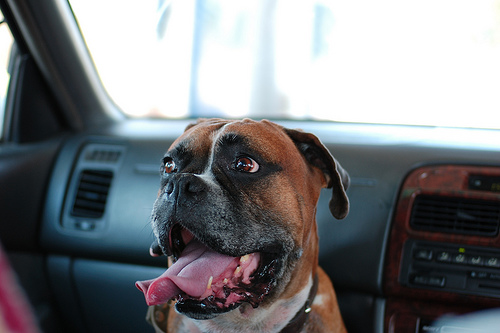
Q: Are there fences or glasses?
A: No, there are no fences or glasses.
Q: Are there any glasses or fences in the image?
A: No, there are no fences or glasses.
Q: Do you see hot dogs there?
A: Yes, there is a hot dog.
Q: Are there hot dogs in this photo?
A: Yes, there is a hot dog.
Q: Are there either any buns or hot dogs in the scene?
A: Yes, there is a hot dog.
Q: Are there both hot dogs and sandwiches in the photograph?
A: No, there is a hot dog but no sandwiches.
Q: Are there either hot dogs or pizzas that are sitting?
A: Yes, the hot dog is sitting.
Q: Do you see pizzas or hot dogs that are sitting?
A: Yes, the hot dog is sitting.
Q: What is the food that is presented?
A: The food is a hot dog.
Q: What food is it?
A: The food is a hot dog.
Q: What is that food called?
A: This is a hot dog.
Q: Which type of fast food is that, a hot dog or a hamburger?
A: This is a hot dog.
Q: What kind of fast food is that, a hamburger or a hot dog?
A: This is a hot dog.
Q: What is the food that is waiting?
A: The food is a hot dog.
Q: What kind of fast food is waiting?
A: The fast food is a hot dog.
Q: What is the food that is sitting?
A: The food is a hot dog.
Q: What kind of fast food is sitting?
A: The fast food is a hot dog.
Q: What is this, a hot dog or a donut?
A: This is a hot dog.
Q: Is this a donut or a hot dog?
A: This is a hot dog.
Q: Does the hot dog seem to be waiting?
A: Yes, the hot dog is waiting.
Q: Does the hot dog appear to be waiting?
A: Yes, the hot dog is waiting.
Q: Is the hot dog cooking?
A: No, the hot dog is waiting.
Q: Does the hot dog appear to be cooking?
A: No, the hot dog is waiting.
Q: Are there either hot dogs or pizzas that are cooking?
A: No, there is a hot dog but it is waiting.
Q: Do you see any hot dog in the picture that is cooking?
A: No, there is a hot dog but it is waiting.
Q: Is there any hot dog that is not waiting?
A: No, there is a hot dog but it is waiting.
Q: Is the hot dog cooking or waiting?
A: The hot dog is waiting.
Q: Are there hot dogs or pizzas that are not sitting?
A: No, there is a hot dog but it is sitting.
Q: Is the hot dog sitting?
A: Yes, the hot dog is sitting.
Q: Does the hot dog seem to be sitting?
A: Yes, the hot dog is sitting.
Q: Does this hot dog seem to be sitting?
A: Yes, the hot dog is sitting.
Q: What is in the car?
A: The hot dog is in the car.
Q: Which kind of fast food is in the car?
A: The food is a hot dog.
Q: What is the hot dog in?
A: The hot dog is in the car.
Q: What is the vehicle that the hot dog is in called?
A: The vehicle is a car.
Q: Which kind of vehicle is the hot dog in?
A: The hot dog is in the car.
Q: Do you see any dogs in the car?
A: No, there is a hot dog in the car.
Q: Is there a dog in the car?
A: No, there is a hot dog in the car.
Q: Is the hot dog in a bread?
A: No, the hot dog is in the car.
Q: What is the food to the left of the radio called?
A: The food is a hot dog.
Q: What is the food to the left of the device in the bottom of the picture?
A: The food is a hot dog.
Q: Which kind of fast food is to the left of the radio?
A: The food is a hot dog.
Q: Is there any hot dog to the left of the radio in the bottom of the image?
A: Yes, there is a hot dog to the left of the radio.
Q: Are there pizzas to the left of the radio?
A: No, there is a hot dog to the left of the radio.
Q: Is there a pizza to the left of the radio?
A: No, there is a hot dog to the left of the radio.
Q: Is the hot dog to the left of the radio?
A: Yes, the hot dog is to the left of the radio.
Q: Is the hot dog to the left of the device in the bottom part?
A: Yes, the hot dog is to the left of the radio.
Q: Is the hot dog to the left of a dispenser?
A: No, the hot dog is to the left of the radio.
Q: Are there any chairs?
A: No, there are no chairs.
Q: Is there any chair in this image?
A: No, there are no chairs.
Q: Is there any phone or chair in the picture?
A: No, there are no chairs or phones.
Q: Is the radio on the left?
A: No, the radio is on the right of the image.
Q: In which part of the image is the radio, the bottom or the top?
A: The radio is in the bottom of the image.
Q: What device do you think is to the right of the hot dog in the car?
A: The device is a radio.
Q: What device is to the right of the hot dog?
A: The device is a radio.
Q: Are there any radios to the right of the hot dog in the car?
A: Yes, there is a radio to the right of the hot dog.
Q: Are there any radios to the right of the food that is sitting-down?
A: Yes, there is a radio to the right of the hot dog.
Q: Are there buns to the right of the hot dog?
A: No, there is a radio to the right of the hot dog.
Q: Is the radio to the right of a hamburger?
A: No, the radio is to the right of a hot dog.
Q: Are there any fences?
A: No, there are no fences.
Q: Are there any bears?
A: No, there are no bears.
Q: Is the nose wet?
A: Yes, the nose is wet.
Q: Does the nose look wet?
A: Yes, the nose is wet.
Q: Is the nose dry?
A: No, the nose is wet.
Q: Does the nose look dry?
A: No, the nose is wet.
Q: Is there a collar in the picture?
A: Yes, there is a collar.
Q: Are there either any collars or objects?
A: Yes, there is a collar.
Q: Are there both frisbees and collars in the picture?
A: No, there is a collar but no frisbees.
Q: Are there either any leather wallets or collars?
A: Yes, there is a leather collar.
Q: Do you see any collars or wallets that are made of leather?
A: Yes, the collar is made of leather.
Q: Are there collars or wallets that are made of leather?
A: Yes, the collar is made of leather.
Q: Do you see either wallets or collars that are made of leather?
A: Yes, the collar is made of leather.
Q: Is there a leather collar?
A: Yes, there is a collar that is made of leather.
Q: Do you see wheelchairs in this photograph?
A: No, there are no wheelchairs.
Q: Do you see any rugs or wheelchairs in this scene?
A: No, there are no wheelchairs or rugs.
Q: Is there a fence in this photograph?
A: No, there are no fences.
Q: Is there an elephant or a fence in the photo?
A: No, there are no fences or elephants.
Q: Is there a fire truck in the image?
A: No, there are no fire trucks.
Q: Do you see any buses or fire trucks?
A: No, there are no fire trucks or buses.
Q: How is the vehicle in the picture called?
A: The vehicle is a car.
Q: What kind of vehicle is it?
A: The vehicle is a car.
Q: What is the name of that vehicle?
A: This is a car.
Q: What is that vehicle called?
A: This is a car.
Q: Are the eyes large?
A: Yes, the eyes are large.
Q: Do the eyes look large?
A: Yes, the eyes are large.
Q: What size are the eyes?
A: The eyes are large.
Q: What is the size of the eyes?
A: The eyes are large.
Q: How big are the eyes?
A: The eyes are large.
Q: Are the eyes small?
A: No, the eyes are large.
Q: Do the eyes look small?
A: No, the eyes are large.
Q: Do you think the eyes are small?
A: No, the eyes are large.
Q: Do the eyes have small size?
A: No, the eyes are large.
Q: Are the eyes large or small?
A: The eyes are large.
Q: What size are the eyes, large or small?
A: The eyes are large.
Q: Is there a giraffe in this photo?
A: No, there are no giraffes.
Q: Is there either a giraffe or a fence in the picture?
A: No, there are no giraffes or fences.